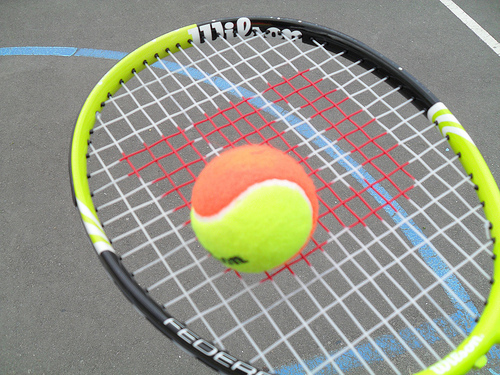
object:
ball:
[190, 144, 321, 276]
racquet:
[71, 17, 496, 371]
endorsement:
[160, 320, 274, 373]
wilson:
[187, 17, 303, 49]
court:
[5, 5, 493, 368]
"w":
[125, 70, 419, 289]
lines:
[3, 45, 497, 368]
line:
[442, 5, 498, 57]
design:
[66, 200, 117, 255]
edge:
[32, 28, 193, 254]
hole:
[149, 47, 166, 63]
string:
[152, 48, 427, 367]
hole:
[186, 40, 195, 47]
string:
[86, 20, 497, 372]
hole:
[118, 78, 127, 89]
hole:
[84, 174, 94, 182]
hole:
[430, 121, 442, 128]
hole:
[469, 170, 475, 181]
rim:
[72, 18, 495, 370]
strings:
[86, 25, 497, 369]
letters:
[185, 22, 303, 47]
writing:
[213, 252, 251, 269]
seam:
[191, 177, 316, 230]